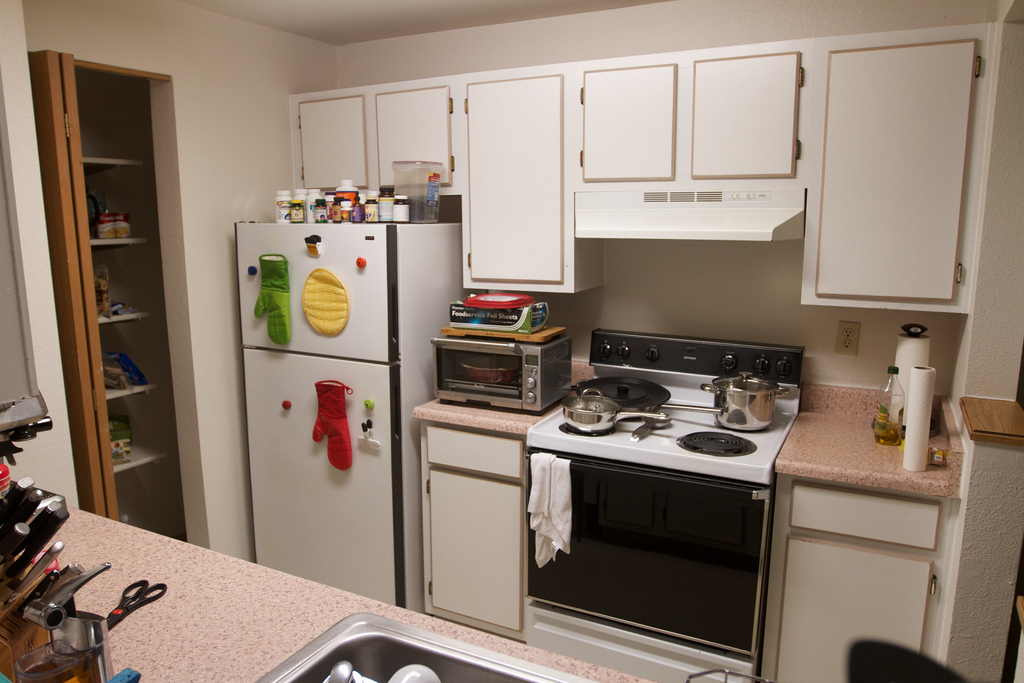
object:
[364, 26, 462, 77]
wall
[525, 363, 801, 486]
stovetop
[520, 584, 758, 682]
anoven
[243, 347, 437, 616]
fridge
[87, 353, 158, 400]
shelf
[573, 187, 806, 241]
rangehood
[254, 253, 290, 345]
ovenmitt